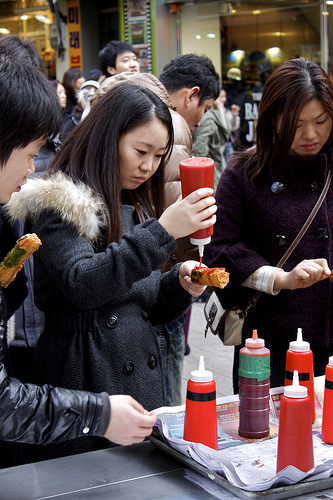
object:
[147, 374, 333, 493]
newspaper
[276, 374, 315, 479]
bottle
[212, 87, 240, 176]
people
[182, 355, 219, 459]
ketchup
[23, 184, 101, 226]
shoulder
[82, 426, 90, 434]
buttons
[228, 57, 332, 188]
hair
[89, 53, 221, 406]
boy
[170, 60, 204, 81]
black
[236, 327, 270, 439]
bottle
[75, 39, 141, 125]
man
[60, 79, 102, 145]
woman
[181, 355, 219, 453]
bottle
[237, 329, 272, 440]
sauces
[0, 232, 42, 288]
stick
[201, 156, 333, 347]
purse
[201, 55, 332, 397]
woman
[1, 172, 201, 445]
coat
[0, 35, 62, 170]
hair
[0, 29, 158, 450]
boy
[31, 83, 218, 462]
woman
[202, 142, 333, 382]
coat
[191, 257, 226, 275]
ketchup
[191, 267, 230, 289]
hotdog